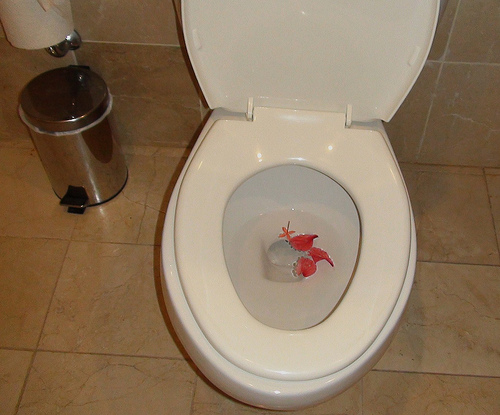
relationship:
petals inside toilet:
[281, 230, 324, 280] [155, 0, 445, 414]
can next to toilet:
[20, 59, 137, 214] [155, 0, 445, 414]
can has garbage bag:
[16, 64, 129, 217] [18, 64, 110, 123]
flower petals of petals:
[291, 254, 319, 278] [306, 246, 336, 268]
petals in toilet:
[276, 225, 336, 283] [155, 0, 445, 414]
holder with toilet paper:
[21, 20, 100, 56] [0, 0, 76, 51]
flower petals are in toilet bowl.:
[278, 218, 338, 277] [154, 108, 418, 410]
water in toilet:
[238, 203, 348, 321] [153, 0, 415, 415]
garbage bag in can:
[15, 94, 124, 136] [12, 64, 131, 216]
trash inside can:
[12, 65, 132, 214] [18, 62, 133, 223]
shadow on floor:
[403, 280, 428, 362] [0, 138, 499, 413]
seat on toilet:
[172, 101, 417, 381] [155, 0, 445, 414]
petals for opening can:
[285, 232, 318, 251] [16, 64, 129, 217]